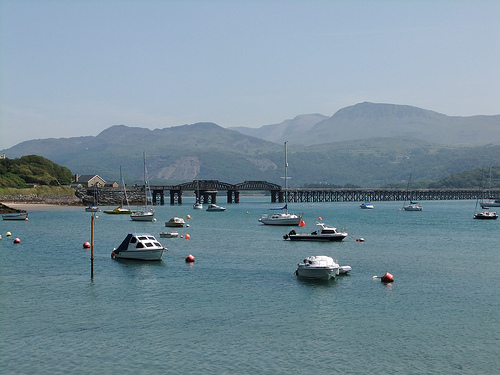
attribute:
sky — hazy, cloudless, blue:
[1, 1, 492, 150]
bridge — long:
[76, 180, 500, 204]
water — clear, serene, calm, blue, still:
[2, 193, 500, 373]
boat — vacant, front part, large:
[113, 232, 165, 263]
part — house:
[72, 173, 122, 191]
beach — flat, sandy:
[2, 200, 89, 208]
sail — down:
[279, 138, 294, 214]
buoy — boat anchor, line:
[165, 247, 197, 265]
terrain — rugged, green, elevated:
[2, 153, 77, 200]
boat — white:
[297, 253, 344, 281]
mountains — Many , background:
[1, 102, 499, 196]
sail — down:
[139, 145, 153, 213]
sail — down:
[116, 167, 131, 209]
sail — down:
[192, 174, 205, 205]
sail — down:
[488, 165, 495, 199]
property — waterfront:
[68, 174, 123, 201]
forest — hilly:
[1, 140, 498, 190]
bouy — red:
[182, 253, 198, 265]